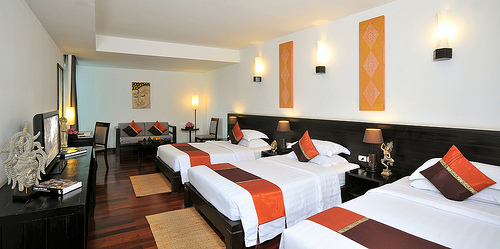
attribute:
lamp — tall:
[184, 88, 204, 137]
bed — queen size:
[207, 158, 306, 206]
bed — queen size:
[373, 172, 459, 234]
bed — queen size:
[177, 120, 265, 155]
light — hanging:
[300, 40, 338, 80]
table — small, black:
[338, 158, 410, 206]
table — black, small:
[258, 144, 293, 158]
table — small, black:
[180, 126, 198, 140]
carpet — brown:
[143, 206, 225, 248]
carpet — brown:
[128, 169, 173, 199]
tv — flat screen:
[31, 114, 65, 167]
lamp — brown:
[353, 116, 403, 181]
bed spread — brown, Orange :
[218, 160, 262, 206]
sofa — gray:
[111, 118, 178, 156]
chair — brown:
[91, 122, 111, 160]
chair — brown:
[197, 117, 219, 143]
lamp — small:
[364, 127, 382, 170]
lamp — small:
[226, 111, 238, 136]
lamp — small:
[273, 116, 290, 151]